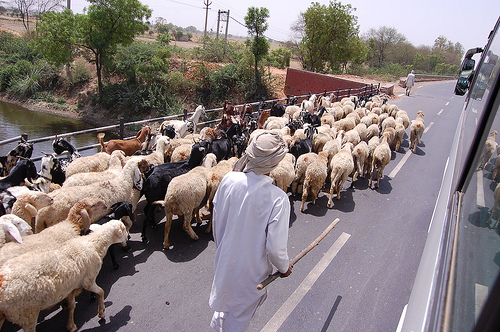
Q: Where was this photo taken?
A: On a road.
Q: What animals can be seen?
A: Sheep.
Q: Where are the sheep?
A: Walking on the road.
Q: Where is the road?
A: On a bridge.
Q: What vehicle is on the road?
A: A bus.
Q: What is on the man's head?
A: A scarf.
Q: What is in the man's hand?
A: A stick.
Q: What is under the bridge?
A: Water.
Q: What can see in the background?
A: Trees.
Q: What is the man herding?
A: Sheep.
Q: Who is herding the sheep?
A: The man.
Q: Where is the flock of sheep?
A: The road.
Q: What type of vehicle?
A: Bus.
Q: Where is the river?
A: On the left.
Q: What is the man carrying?
A: Walking stick.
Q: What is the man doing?
A: Guiding the sheep.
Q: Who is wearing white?
A: The man.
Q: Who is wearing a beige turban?
A: The man.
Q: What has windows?
A: The bus.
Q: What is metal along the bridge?
A: A guard rail.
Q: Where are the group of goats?
A: On the bridge.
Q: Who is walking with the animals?
A: A man.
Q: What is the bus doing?
A: Driving.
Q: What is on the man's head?
A: A turban.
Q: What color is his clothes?
A: White.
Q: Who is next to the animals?
A: A man.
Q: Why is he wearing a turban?
A: Religion.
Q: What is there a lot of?
A: Animals.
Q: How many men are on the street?
A: 2.